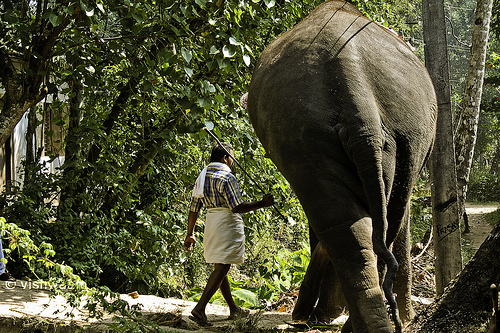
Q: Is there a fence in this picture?
A: No, there are no fences.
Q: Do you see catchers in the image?
A: No, there are no catchers.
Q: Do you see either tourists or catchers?
A: No, there are no catchers or tourists.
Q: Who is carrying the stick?
A: The man is carrying the stick.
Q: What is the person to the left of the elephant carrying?
A: The man is carrying a stick.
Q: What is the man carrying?
A: The man is carrying a stick.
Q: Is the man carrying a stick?
A: Yes, the man is carrying a stick.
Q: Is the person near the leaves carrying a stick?
A: Yes, the man is carrying a stick.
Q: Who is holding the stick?
A: The man is holding the stick.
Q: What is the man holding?
A: The man is holding the stick.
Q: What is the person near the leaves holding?
A: The man is holding the stick.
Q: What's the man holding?
A: The man is holding the stick.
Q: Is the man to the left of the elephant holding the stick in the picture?
A: Yes, the man is holding the stick.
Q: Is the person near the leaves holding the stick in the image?
A: Yes, the man is holding the stick.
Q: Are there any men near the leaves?
A: Yes, there is a man near the leaves.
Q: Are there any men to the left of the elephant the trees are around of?
A: Yes, there is a man to the left of the elephant.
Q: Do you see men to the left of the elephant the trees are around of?
A: Yes, there is a man to the left of the elephant.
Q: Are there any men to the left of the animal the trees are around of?
A: Yes, there is a man to the left of the elephant.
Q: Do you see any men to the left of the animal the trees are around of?
A: Yes, there is a man to the left of the elephant.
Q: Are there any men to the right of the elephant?
A: No, the man is to the left of the elephant.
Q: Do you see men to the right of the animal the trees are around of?
A: No, the man is to the left of the elephant.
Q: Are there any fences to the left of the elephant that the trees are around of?
A: No, there is a man to the left of the elephant.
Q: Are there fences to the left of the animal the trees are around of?
A: No, there is a man to the left of the elephant.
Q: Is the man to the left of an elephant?
A: Yes, the man is to the left of an elephant.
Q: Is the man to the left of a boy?
A: No, the man is to the left of an elephant.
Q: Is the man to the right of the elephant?
A: No, the man is to the left of the elephant.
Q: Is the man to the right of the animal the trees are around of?
A: No, the man is to the left of the elephant.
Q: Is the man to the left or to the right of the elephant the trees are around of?
A: The man is to the left of the elephant.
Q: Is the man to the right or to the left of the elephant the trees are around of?
A: The man is to the left of the elephant.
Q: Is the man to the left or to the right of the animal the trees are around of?
A: The man is to the left of the elephant.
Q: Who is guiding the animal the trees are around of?
A: The man is guiding the elephant.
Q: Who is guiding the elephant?
A: The man is guiding the elephant.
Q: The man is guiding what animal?
A: The man is guiding the elephant.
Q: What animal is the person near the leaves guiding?
A: The man is guiding the elephant.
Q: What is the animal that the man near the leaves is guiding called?
A: The animal is an elephant.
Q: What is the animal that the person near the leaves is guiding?
A: The animal is an elephant.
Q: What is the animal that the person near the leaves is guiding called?
A: The animal is an elephant.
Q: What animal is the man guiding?
A: The man is guiding the elephant.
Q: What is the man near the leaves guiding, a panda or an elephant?
A: The man is guiding an elephant.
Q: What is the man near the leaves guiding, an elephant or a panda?
A: The man is guiding an elephant.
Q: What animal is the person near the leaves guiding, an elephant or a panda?
A: The man is guiding an elephant.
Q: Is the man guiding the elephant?
A: Yes, the man is guiding the elephant.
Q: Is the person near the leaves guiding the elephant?
A: Yes, the man is guiding the elephant.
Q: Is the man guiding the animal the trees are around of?
A: Yes, the man is guiding the elephant.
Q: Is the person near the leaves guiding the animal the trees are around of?
A: Yes, the man is guiding the elephant.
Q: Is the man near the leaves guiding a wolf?
A: No, the man is guiding the elephant.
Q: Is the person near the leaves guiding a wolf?
A: No, the man is guiding the elephant.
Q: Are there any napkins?
A: No, there are no napkins.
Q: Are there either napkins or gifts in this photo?
A: No, there are no napkins or gifts.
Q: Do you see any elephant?
A: Yes, there is an elephant.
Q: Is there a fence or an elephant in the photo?
A: Yes, there is an elephant.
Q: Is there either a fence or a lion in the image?
A: No, there are no fences or lions.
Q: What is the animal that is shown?
A: The animal is an elephant.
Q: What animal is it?
A: The animal is an elephant.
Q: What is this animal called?
A: This is an elephant.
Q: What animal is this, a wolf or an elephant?
A: This is an elephant.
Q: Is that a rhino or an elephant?
A: That is an elephant.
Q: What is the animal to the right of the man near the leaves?
A: The animal is an elephant.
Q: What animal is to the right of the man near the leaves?
A: The animal is an elephant.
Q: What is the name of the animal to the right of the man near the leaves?
A: The animal is an elephant.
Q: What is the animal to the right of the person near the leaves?
A: The animal is an elephant.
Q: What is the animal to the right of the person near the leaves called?
A: The animal is an elephant.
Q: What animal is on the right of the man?
A: The animal is an elephant.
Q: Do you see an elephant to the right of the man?
A: Yes, there is an elephant to the right of the man.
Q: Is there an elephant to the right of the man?
A: Yes, there is an elephant to the right of the man.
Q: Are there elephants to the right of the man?
A: Yes, there is an elephant to the right of the man.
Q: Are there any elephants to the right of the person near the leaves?
A: Yes, there is an elephant to the right of the man.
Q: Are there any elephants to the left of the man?
A: No, the elephant is to the right of the man.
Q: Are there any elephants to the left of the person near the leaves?
A: No, the elephant is to the right of the man.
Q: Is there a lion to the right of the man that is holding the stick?
A: No, there is an elephant to the right of the man.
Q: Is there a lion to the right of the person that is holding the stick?
A: No, there is an elephant to the right of the man.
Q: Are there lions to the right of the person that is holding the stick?
A: No, there is an elephant to the right of the man.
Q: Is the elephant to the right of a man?
A: Yes, the elephant is to the right of a man.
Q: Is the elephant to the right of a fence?
A: No, the elephant is to the right of a man.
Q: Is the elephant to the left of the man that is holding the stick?
A: No, the elephant is to the right of the man.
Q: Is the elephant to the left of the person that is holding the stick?
A: No, the elephant is to the right of the man.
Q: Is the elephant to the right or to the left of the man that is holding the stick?
A: The elephant is to the right of the man.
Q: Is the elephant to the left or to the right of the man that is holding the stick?
A: The elephant is to the right of the man.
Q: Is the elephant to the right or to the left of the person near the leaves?
A: The elephant is to the right of the man.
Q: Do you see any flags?
A: No, there are no flags.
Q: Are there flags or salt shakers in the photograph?
A: No, there are no flags or salt shakers.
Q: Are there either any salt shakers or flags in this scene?
A: No, there are no flags or salt shakers.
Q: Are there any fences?
A: No, there are no fences.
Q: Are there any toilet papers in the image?
A: No, there are no toilet papers.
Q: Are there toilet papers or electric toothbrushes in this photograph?
A: No, there are no toilet papers or electric toothbrushes.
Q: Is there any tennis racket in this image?
A: No, there are no rackets.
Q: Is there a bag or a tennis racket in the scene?
A: No, there are no rackets or bags.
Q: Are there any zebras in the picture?
A: No, there are no zebras.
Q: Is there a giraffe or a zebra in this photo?
A: No, there are no zebras or giraffes.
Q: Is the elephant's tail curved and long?
A: Yes, the tail is curved and long.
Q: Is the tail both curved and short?
A: No, the tail is curved but long.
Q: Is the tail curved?
A: Yes, the tail is curved.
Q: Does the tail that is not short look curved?
A: Yes, the tail is curved.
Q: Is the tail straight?
A: No, the tail is curved.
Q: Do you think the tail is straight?
A: No, the tail is curved.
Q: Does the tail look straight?
A: No, the tail is curved.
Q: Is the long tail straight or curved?
A: The tail is curved.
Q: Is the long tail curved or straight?
A: The tail is curved.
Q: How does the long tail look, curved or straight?
A: The tail is curved.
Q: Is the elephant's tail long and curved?
A: Yes, the tail is long and curved.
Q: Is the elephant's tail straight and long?
A: No, the tail is long but curved.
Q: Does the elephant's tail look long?
A: Yes, the tail is long.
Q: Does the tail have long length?
A: Yes, the tail is long.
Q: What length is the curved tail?
A: The tail is long.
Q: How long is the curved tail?
A: The tail is long.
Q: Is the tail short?
A: No, the tail is long.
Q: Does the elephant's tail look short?
A: No, the tail is long.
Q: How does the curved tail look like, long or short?
A: The tail is long.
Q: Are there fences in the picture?
A: No, there are no fences.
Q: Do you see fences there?
A: No, there are no fences.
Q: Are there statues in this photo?
A: No, there are no statues.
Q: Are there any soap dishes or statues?
A: No, there are no statues or soap dishes.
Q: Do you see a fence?
A: No, there are no fences.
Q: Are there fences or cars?
A: No, there are no fences or cars.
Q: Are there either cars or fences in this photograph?
A: No, there are no fences or cars.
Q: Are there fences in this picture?
A: No, there are no fences.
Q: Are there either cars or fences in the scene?
A: No, there are no fences or cars.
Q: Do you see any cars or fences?
A: No, there are no fences or cars.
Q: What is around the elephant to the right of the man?
A: The trees are around the elephant.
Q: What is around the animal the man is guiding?
A: The trees are around the elephant.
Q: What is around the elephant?
A: The trees are around the elephant.